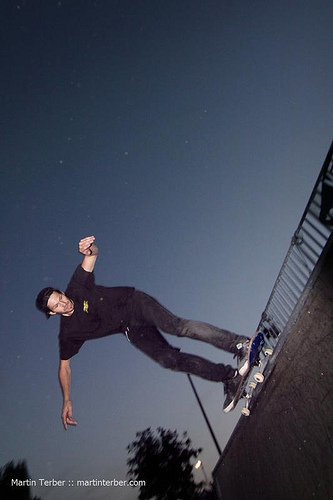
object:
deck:
[233, 331, 273, 418]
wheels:
[240, 348, 274, 417]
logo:
[83, 300, 89, 313]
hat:
[34, 286, 53, 320]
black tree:
[122, 426, 204, 500]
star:
[60, 160, 63, 164]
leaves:
[155, 453, 173, 481]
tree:
[125, 422, 210, 500]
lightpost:
[191, 455, 215, 495]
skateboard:
[237, 329, 274, 416]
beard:
[63, 300, 75, 313]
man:
[35, 234, 255, 431]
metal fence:
[296, 214, 332, 252]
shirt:
[57, 262, 135, 360]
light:
[195, 459, 202, 470]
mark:
[83, 300, 89, 313]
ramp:
[233, 280, 321, 491]